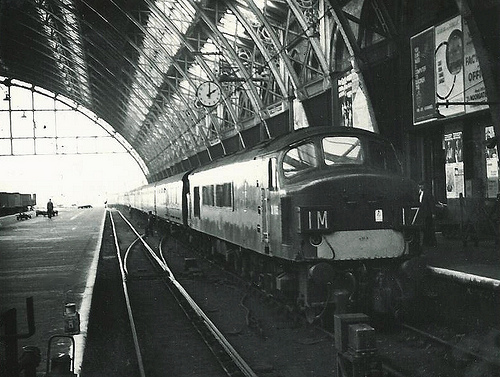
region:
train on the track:
[112, 132, 423, 324]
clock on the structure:
[194, 80, 229, 112]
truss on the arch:
[278, 18, 305, 53]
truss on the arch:
[286, 54, 328, 84]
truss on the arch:
[198, 1, 240, 45]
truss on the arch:
[183, 30, 203, 51]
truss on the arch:
[168, 0, 185, 27]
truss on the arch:
[163, 8, 185, 28]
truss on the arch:
[134, 15, 156, 39]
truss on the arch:
[167, 33, 181, 61]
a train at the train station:
[57, 126, 449, 309]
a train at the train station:
[91, 121, 424, 356]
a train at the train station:
[89, 149, 405, 335]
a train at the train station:
[100, 114, 435, 359]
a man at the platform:
[34, 181, 72, 236]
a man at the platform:
[21, 187, 63, 230]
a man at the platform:
[25, 189, 61, 236]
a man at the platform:
[31, 187, 65, 219]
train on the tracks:
[108, 128, 455, 329]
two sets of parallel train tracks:
[98, 204, 477, 375]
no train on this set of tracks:
[103, 208, 253, 375]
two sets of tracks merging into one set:
[123, 223, 180, 280]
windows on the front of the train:
[276, 137, 404, 176]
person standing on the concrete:
[42, 195, 57, 220]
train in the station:
[85, 118, 462, 332]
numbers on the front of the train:
[397, 203, 422, 228]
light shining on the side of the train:
[181, 154, 275, 186]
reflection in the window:
[318, 135, 366, 165]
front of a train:
[269, 105, 446, 282]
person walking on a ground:
[36, 183, 66, 237]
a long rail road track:
[85, 176, 227, 374]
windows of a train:
[289, 128, 411, 192]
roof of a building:
[27, 13, 364, 128]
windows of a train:
[195, 168, 240, 206]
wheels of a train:
[186, 223, 354, 333]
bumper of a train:
[300, 202, 447, 313]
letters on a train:
[292, 205, 436, 243]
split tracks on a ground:
[112, 213, 189, 291]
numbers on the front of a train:
[389, 201, 428, 230]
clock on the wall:
[191, 78, 222, 110]